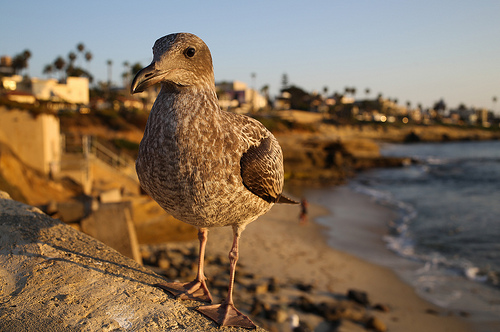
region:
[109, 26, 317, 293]
gray bird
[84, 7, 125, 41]
white clouds in blue sky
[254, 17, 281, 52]
white clouds in blue sky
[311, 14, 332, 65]
white clouds in blue sky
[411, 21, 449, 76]
white clouds in blue sky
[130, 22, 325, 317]
A small brown bird on a rock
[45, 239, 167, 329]
A large rock below the bird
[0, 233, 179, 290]
A thin black shadow of the bird on the rock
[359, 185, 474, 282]
A small wave crashing onto the shore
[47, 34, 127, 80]
Large green palm trees in the background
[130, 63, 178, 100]
A long brown beak on the bird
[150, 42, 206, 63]
Small, black, beady eyes on the bird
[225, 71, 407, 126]
A row of buildings in the distance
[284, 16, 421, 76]
An open, clear blue sky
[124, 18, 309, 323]
bird perched on a rock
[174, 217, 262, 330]
legs of a bird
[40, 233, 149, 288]
shadow from bird's legs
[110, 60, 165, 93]
beak of a bird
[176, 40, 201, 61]
left eye of a bird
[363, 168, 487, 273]
water of an ocean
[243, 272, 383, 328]
rocks on the beach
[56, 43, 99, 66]
palm trees in the distance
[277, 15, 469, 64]
blue sky in the background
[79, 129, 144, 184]
stairs from the sand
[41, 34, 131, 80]
palm trees in background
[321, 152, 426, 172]
rocks on the shoreline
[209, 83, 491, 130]
buildings in the background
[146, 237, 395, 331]
seaweed and debris on sand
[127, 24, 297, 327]
brown sea bird in center of picture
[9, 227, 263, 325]
rock bird is standing on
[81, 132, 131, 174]
stairway down to beach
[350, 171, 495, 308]
breaking waves near shore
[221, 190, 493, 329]
brown sand on beach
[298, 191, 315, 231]
person standing on the beach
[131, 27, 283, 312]
a bird on a rock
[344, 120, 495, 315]
a ocean sea shore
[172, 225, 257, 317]
the legs of a bird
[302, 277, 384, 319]
rocks on the sand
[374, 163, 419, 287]
waves on a beach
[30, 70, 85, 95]
a building in the distance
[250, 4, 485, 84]
a clear blue sky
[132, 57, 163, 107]
the beck of a bird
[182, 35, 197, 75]
a eye of a bird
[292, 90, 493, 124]
houses in the distance